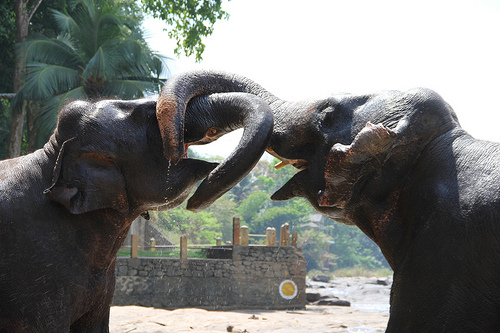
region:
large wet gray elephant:
[0, 93, 273, 331]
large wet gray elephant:
[156, 67, 498, 332]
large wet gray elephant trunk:
[164, 92, 274, 212]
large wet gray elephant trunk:
[155, 67, 292, 159]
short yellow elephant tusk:
[274, 161, 291, 168]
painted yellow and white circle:
[280, 279, 297, 300]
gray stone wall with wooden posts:
[106, 217, 304, 307]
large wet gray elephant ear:
[44, 135, 130, 219]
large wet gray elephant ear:
[318, 120, 413, 209]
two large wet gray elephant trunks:
[156, 69, 306, 214]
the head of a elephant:
[11, 55, 289, 269]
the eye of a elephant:
[111, 88, 168, 141]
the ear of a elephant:
[31, 128, 143, 231]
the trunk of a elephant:
[174, 101, 298, 220]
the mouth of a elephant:
[258, 135, 359, 217]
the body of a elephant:
[13, 33, 304, 313]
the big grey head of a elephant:
[20, 43, 249, 313]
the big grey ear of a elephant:
[16, 118, 145, 253]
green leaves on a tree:
[38, 0, 215, 38]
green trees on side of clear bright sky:
[2, 0, 497, 145]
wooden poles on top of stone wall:
[115, 211, 307, 306]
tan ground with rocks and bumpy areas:
[107, 275, 387, 330]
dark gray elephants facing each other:
[5, 65, 495, 322]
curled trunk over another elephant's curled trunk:
[150, 65, 300, 212]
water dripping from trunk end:
[157, 136, 182, 236]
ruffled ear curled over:
[315, 115, 390, 235]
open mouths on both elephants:
[166, 126, 312, 206]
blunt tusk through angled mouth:
[263, 147, 293, 198]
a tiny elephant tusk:
[271, 153, 293, 173]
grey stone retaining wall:
[120, 248, 309, 320]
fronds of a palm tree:
[16, 0, 169, 139]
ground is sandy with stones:
[108, 283, 405, 332]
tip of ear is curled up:
[41, 122, 128, 227]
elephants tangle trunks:
[39, 74, 470, 236]